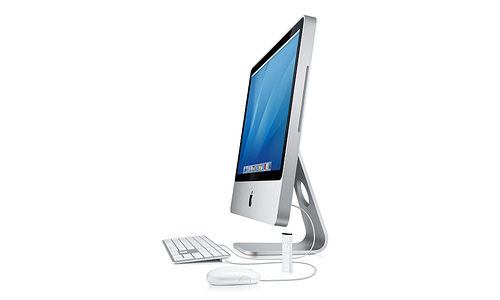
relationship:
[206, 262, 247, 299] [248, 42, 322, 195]
mouse for computer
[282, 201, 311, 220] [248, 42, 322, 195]
usb for computer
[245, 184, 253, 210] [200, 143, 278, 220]
logo at bottom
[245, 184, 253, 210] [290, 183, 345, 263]
logo has stand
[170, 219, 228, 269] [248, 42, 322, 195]
keyboard for computer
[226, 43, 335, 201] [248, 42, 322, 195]
screen for computer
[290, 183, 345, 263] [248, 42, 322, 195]
stand for computer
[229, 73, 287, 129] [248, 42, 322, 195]
monitor for computer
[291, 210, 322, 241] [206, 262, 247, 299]
cord for mouse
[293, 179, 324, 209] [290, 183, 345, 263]
hole in stand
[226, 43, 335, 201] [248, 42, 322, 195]
screen of computer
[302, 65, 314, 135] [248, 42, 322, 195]
disk drive on computer